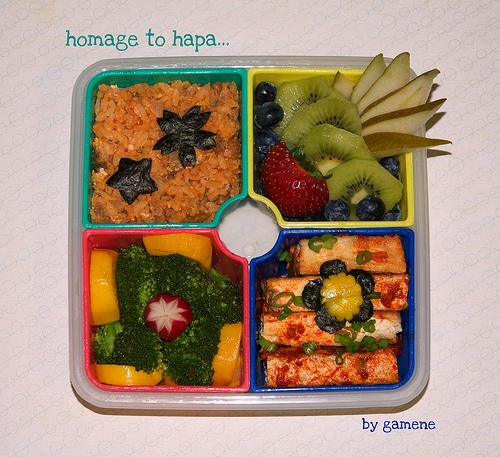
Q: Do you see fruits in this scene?
A: Yes, there is a fruit.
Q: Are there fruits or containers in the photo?
A: Yes, there is a fruit.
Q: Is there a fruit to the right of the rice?
A: Yes, there is a fruit to the right of the rice.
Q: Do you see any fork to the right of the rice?
A: No, there is a fruit to the right of the rice.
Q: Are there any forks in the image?
A: No, there are no forks.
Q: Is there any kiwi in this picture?
A: Yes, there is a kiwi.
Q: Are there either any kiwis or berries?
A: Yes, there is a kiwi.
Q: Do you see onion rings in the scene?
A: No, there are no onion rings.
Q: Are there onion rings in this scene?
A: No, there are no onion rings.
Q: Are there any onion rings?
A: No, there are no onion rings.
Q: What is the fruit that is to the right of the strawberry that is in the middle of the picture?
A: The fruit is a kiwi.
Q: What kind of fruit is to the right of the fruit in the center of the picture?
A: The fruit is a kiwi.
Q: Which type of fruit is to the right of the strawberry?
A: The fruit is a kiwi.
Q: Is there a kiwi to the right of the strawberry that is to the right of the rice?
A: Yes, there is a kiwi to the right of the strawberry.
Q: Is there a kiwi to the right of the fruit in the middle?
A: Yes, there is a kiwi to the right of the strawberry.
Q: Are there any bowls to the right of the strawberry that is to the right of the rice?
A: No, there is a kiwi to the right of the strawberry.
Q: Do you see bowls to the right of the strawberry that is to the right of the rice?
A: No, there is a kiwi to the right of the strawberry.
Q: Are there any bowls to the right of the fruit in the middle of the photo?
A: No, there is a kiwi to the right of the strawberry.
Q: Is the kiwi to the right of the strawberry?
A: Yes, the kiwi is to the right of the strawberry.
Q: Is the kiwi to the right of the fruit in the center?
A: Yes, the kiwi is to the right of the strawberry.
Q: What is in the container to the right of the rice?
A: The kiwi is in the container.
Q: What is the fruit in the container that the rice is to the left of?
A: The fruit is a kiwi.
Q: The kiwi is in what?
A: The kiwi is in the container.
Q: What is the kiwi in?
A: The kiwi is in the container.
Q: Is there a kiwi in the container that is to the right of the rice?
A: Yes, there is a kiwi in the container.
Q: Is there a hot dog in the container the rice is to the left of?
A: No, there is a kiwi in the container.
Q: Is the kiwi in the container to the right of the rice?
A: Yes, the kiwi is in the container.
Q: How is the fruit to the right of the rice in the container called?
A: The fruit is a kiwi.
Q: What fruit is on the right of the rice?
A: The fruit is a kiwi.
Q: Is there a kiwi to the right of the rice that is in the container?
A: Yes, there is a kiwi to the right of the rice.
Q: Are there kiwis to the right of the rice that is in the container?
A: Yes, there is a kiwi to the right of the rice.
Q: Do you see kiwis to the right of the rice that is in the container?
A: Yes, there is a kiwi to the right of the rice.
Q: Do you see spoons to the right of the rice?
A: No, there is a kiwi to the right of the rice.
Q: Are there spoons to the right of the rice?
A: No, there is a kiwi to the right of the rice.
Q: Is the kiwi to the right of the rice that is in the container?
A: Yes, the kiwi is to the right of the rice.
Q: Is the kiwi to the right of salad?
A: No, the kiwi is to the right of the rice.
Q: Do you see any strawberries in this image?
A: Yes, there is a strawberry.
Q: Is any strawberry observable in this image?
A: Yes, there is a strawberry.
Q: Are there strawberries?
A: Yes, there is a strawberry.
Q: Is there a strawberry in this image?
A: Yes, there is a strawberry.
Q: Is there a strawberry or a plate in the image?
A: Yes, there is a strawberry.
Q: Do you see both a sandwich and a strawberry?
A: No, there is a strawberry but no sandwiches.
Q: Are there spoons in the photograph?
A: No, there are no spoons.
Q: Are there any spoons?
A: No, there are no spoons.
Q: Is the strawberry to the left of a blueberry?
A: Yes, the strawberry is to the left of a blueberry.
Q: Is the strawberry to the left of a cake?
A: No, the strawberry is to the left of a blueberry.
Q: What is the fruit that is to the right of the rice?
A: The fruit is a strawberry.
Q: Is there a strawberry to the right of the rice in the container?
A: Yes, there is a strawberry to the right of the rice.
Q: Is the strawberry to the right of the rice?
A: Yes, the strawberry is to the right of the rice.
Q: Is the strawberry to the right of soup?
A: No, the strawberry is to the right of the rice.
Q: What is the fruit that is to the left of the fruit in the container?
A: The fruit is a strawberry.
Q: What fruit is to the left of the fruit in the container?
A: The fruit is a strawberry.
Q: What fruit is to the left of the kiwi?
A: The fruit is a strawberry.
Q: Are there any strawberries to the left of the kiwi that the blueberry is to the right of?
A: Yes, there is a strawberry to the left of the kiwi.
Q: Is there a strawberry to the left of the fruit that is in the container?
A: Yes, there is a strawberry to the left of the kiwi.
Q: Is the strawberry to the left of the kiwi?
A: Yes, the strawberry is to the left of the kiwi.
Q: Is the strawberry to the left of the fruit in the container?
A: Yes, the strawberry is to the left of the kiwi.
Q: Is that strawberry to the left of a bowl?
A: No, the strawberry is to the left of the kiwi.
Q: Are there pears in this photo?
A: Yes, there are pears.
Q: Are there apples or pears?
A: Yes, there are pears.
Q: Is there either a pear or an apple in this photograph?
A: Yes, there are pears.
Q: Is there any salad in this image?
A: No, there is no salad.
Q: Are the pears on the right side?
A: Yes, the pears are on the right of the image.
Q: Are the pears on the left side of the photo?
A: No, the pears are on the right of the image.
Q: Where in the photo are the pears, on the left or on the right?
A: The pears are on the right of the image.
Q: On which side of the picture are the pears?
A: The pears are on the right of the image.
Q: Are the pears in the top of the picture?
A: Yes, the pears are in the top of the image.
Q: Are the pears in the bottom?
A: No, the pears are in the top of the image.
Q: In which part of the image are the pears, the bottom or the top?
A: The pears are in the top of the image.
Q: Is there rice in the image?
A: Yes, there is rice.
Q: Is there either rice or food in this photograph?
A: Yes, there is rice.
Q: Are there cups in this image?
A: No, there are no cups.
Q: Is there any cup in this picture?
A: No, there are no cups.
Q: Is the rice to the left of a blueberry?
A: Yes, the rice is to the left of a blueberry.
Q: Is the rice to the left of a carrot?
A: No, the rice is to the left of a blueberry.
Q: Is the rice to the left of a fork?
A: No, the rice is to the left of a blueberry.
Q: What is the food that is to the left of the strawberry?
A: The food is rice.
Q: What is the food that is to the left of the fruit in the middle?
A: The food is rice.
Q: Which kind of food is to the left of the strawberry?
A: The food is rice.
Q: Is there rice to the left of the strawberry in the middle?
A: Yes, there is rice to the left of the strawberry.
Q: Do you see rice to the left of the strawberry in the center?
A: Yes, there is rice to the left of the strawberry.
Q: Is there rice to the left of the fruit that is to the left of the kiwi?
A: Yes, there is rice to the left of the strawberry.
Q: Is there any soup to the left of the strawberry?
A: No, there is rice to the left of the strawberry.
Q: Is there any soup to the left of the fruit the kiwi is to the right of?
A: No, there is rice to the left of the strawberry.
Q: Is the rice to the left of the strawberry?
A: Yes, the rice is to the left of the strawberry.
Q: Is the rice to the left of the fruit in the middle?
A: Yes, the rice is to the left of the strawberry.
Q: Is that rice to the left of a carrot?
A: No, the rice is to the left of the strawberry.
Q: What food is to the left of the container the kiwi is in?
A: The food is rice.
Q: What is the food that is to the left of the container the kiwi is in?
A: The food is rice.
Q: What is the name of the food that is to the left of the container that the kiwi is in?
A: The food is rice.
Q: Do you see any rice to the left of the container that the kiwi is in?
A: Yes, there is rice to the left of the container.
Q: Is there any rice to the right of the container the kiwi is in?
A: No, the rice is to the left of the container.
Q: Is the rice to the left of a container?
A: Yes, the rice is to the left of a container.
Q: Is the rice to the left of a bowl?
A: No, the rice is to the left of a container.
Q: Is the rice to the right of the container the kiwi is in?
A: No, the rice is to the left of the container.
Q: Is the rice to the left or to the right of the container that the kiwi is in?
A: The rice is to the left of the container.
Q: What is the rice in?
A: The rice is in the container.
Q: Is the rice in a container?
A: Yes, the rice is in a container.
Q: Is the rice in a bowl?
A: No, the rice is in a container.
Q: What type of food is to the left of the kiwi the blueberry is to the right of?
A: The food is rice.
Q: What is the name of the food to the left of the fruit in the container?
A: The food is rice.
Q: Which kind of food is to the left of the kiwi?
A: The food is rice.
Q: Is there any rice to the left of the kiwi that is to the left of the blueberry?
A: Yes, there is rice to the left of the kiwi.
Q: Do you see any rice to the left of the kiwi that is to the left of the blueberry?
A: Yes, there is rice to the left of the kiwi.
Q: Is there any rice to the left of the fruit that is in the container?
A: Yes, there is rice to the left of the kiwi.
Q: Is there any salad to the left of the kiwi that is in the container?
A: No, there is rice to the left of the kiwi.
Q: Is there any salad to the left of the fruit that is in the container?
A: No, there is rice to the left of the kiwi.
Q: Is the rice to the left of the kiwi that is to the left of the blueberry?
A: Yes, the rice is to the left of the kiwi.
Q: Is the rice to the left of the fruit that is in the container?
A: Yes, the rice is to the left of the kiwi.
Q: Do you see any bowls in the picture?
A: No, there are no bowls.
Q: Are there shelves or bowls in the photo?
A: No, there are no bowls or shelves.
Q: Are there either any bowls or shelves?
A: No, there are no bowls or shelves.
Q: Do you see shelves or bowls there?
A: No, there are no bowls or shelves.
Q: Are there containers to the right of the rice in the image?
A: Yes, there is a container to the right of the rice.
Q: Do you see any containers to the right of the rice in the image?
A: Yes, there is a container to the right of the rice.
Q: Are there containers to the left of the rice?
A: No, the container is to the right of the rice.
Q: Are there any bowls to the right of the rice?
A: No, there is a container to the right of the rice.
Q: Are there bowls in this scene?
A: No, there are no bowls.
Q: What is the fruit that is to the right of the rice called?
A: The fruit is a blueberry.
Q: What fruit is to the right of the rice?
A: The fruit is a blueberry.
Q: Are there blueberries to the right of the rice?
A: Yes, there is a blueberry to the right of the rice.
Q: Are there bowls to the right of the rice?
A: No, there is a blueberry to the right of the rice.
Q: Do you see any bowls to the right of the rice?
A: No, there is a blueberry to the right of the rice.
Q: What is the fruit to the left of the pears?
A: The fruit is a blueberry.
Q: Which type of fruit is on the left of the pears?
A: The fruit is a blueberry.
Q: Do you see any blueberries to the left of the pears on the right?
A: Yes, there is a blueberry to the left of the pears.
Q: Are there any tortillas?
A: No, there are no tortillas.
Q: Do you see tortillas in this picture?
A: No, there are no tortillas.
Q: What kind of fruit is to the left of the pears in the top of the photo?
A: The fruit is a blueberry.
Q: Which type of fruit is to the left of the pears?
A: The fruit is a blueberry.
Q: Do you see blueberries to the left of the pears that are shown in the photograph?
A: Yes, there is a blueberry to the left of the pears.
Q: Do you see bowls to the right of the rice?
A: No, there is a blueberry to the right of the rice.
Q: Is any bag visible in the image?
A: No, there are no bags.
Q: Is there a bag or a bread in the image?
A: No, there are no bags or breads.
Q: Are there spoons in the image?
A: No, there are no spoons.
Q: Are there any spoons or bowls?
A: No, there are no spoons or bowls.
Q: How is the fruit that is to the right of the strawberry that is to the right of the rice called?
A: The fruit is a blueberry.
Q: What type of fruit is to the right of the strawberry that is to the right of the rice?
A: The fruit is a blueberry.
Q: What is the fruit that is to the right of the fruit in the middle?
A: The fruit is a blueberry.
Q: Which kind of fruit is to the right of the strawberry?
A: The fruit is a blueberry.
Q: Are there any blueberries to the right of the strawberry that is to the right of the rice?
A: Yes, there is a blueberry to the right of the strawberry.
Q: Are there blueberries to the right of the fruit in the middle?
A: Yes, there is a blueberry to the right of the strawberry.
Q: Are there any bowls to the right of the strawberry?
A: No, there is a blueberry to the right of the strawberry.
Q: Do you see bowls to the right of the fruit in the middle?
A: No, there is a blueberry to the right of the strawberry.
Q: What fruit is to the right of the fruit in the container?
A: The fruit is a blueberry.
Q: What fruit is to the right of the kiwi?
A: The fruit is a blueberry.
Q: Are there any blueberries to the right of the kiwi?
A: Yes, there is a blueberry to the right of the kiwi.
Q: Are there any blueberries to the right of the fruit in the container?
A: Yes, there is a blueberry to the right of the kiwi.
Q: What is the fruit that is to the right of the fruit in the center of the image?
A: The fruit is a blueberry.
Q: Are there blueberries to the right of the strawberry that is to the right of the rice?
A: Yes, there is a blueberry to the right of the strawberry.